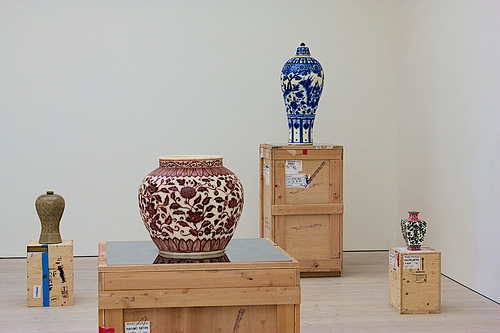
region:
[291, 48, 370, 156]
a tall blue vase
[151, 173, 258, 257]
a red and white vase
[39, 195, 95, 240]
a tall brown vase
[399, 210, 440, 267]
a small multi-colored vase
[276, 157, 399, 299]
a tall wooden crate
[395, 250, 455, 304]
a small wooden crate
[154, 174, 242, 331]
a red and white vase on a crate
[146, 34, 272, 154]
a white colored wall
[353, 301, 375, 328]
a light colored wood floor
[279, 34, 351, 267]
a tall blue and white vase on top of a wooden crate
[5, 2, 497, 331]
a scene indoors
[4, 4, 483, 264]
a white wall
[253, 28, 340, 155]
a blue and white vase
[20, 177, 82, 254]
a green vase on the left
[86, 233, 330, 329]
a tan crate on the foreground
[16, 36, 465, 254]
four vases on stands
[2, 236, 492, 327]
a clean wood floor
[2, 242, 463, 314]
two small crates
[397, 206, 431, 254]
a small vase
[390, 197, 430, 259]
small vase on a crate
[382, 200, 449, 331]
small vase on a box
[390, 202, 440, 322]
small vase on a wooden box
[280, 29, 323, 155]
a tall blue vase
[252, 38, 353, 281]
blue vase on a box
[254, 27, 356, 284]
blue vase on a crate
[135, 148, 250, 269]
vase on a slick surface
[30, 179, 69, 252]
ceramic object on a box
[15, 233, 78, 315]
box with a blue stripe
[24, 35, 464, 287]
four vases on crates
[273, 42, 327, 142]
a blue and white vase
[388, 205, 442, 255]
a purple and white vase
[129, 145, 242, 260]
a rose and white vase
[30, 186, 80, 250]
a ceramic vase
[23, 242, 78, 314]
a wooden crate with blue tape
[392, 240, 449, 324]
a wooden crate with white sticker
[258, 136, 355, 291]
a vertical standing crate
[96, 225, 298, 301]
a mirror under the rose vase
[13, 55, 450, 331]
a room full of ceramic pottery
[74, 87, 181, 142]
a white painted wall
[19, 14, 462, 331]
A collection of vases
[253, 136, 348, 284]
raw wood crates used as display tables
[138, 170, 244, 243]
oriental flower and vine pattern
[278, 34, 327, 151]
Ming blue oriental ginger jar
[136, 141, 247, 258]
Larger ginger pot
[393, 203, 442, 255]
smaller black and white vase with coral accent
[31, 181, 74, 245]
stoneware pot with small top opening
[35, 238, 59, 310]
one crate has a blue stripe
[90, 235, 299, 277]
crates are topped with reflecting glass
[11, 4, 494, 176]
plain white painted walls